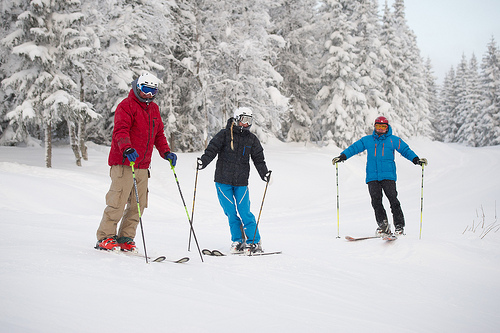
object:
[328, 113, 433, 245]
person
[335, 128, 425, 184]
coat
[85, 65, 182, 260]
man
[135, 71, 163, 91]
helmet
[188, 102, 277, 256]
woman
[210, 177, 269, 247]
pants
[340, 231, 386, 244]
skis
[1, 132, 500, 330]
snow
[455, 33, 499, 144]
trees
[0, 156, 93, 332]
ground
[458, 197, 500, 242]
weeds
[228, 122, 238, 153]
braid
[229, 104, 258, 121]
helmet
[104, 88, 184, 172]
coat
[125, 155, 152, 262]
pole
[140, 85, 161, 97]
goggles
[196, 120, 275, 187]
coat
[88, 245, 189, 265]
skis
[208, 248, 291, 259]
skis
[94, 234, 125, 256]
ski shoes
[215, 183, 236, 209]
stripe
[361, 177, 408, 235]
pants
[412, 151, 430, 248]
poles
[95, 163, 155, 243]
pants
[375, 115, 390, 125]
helmet